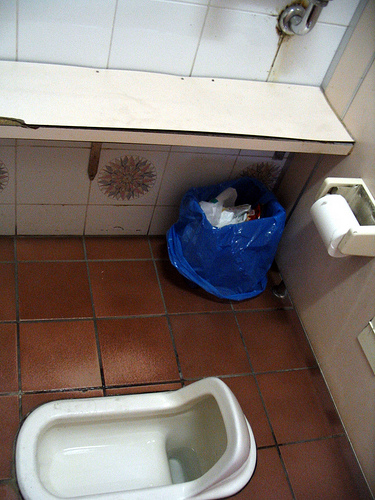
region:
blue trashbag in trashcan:
[160, 163, 290, 301]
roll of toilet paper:
[310, 194, 353, 261]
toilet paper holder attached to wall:
[313, 173, 374, 258]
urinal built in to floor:
[17, 381, 260, 499]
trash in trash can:
[199, 179, 260, 229]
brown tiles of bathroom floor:
[8, 236, 362, 492]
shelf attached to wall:
[7, 61, 348, 154]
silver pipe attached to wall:
[268, 5, 328, 33]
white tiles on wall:
[7, 8, 307, 253]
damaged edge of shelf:
[1, 113, 351, 158]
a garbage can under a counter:
[135, 122, 296, 308]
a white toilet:
[18, 392, 266, 497]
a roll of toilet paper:
[306, 166, 371, 268]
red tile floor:
[16, 291, 171, 366]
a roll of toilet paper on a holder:
[316, 166, 373, 273]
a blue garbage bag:
[155, 189, 288, 303]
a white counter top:
[0, 63, 345, 173]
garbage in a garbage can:
[177, 176, 280, 254]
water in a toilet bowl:
[149, 431, 212, 496]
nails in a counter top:
[170, 72, 234, 90]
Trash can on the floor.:
[158, 152, 309, 328]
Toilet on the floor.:
[9, 359, 202, 498]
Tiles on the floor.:
[36, 250, 302, 419]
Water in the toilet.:
[31, 387, 265, 487]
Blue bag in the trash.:
[197, 156, 282, 307]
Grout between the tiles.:
[73, 257, 117, 336]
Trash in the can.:
[180, 173, 267, 236]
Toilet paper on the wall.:
[302, 133, 372, 300]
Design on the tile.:
[96, 133, 158, 212]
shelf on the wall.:
[95, 52, 310, 178]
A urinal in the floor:
[26, 229, 274, 497]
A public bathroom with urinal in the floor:
[22, 368, 285, 490]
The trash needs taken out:
[170, 161, 284, 328]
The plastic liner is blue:
[174, 210, 275, 297]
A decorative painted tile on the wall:
[96, 149, 159, 203]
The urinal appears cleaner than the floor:
[18, 390, 278, 496]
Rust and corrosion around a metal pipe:
[262, 2, 347, 51]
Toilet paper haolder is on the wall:
[305, 162, 363, 275]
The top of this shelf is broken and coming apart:
[0, 105, 99, 136]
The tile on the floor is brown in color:
[95, 302, 174, 368]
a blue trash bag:
[151, 189, 332, 332]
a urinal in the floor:
[4, 363, 270, 498]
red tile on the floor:
[11, 235, 356, 498]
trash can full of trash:
[172, 183, 290, 309]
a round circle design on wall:
[90, 145, 167, 218]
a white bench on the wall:
[7, 53, 363, 192]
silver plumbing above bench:
[274, 8, 344, 54]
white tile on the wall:
[1, 3, 276, 248]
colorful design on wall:
[100, 148, 181, 229]